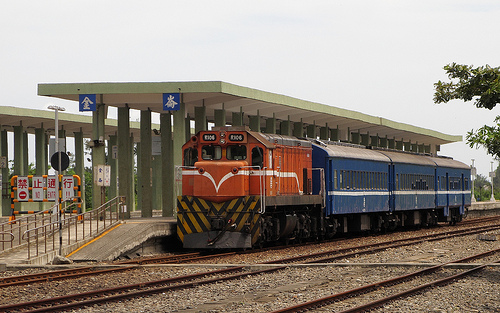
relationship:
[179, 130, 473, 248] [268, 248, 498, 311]
train sitting on track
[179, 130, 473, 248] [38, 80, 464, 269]
train next to station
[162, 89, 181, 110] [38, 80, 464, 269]
sign hanging from station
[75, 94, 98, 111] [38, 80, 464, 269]
sign hanging from station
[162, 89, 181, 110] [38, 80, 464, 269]
sign posted station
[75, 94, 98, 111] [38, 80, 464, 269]
sign posted station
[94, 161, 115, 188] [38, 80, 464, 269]
sign posted station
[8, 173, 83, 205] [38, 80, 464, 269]
sign posted station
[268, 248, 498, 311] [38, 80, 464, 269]
track next to station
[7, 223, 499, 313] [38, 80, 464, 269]
track next to station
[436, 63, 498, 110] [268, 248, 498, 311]
branch next to track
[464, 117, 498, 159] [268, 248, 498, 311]
branch next to track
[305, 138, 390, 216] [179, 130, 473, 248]
car of train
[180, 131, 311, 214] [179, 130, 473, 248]
engine of train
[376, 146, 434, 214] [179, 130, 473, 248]
car of train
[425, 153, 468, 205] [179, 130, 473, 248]
car of train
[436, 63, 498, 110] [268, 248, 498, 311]
branch beside track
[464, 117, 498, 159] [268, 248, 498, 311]
branch beside track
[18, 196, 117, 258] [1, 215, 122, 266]
railing next to ramp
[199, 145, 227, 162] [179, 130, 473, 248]
window of train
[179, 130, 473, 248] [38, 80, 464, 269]
train stopped at station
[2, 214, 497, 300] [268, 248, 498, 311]
gravel under track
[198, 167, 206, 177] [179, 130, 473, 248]
headlight on train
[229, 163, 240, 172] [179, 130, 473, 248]
headlight on train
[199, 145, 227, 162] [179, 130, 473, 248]
window on train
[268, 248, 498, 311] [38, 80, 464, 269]
track near station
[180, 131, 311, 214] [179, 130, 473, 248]
front of train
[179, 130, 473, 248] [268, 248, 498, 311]
train on track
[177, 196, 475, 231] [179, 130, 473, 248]
bottom of train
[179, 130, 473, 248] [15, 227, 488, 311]
train in foreground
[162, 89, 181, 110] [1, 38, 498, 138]
sign in background